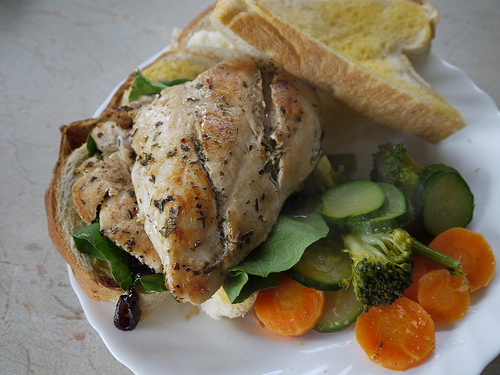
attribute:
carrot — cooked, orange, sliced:
[426, 209, 488, 274]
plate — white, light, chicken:
[45, 58, 464, 363]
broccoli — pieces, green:
[341, 232, 424, 316]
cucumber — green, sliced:
[399, 153, 471, 233]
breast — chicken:
[162, 99, 300, 237]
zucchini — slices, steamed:
[90, 222, 151, 289]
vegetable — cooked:
[190, 150, 484, 359]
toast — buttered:
[305, 14, 408, 105]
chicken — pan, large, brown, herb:
[175, 121, 297, 211]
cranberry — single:
[99, 289, 153, 345]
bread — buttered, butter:
[309, 44, 422, 148]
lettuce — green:
[249, 211, 318, 276]